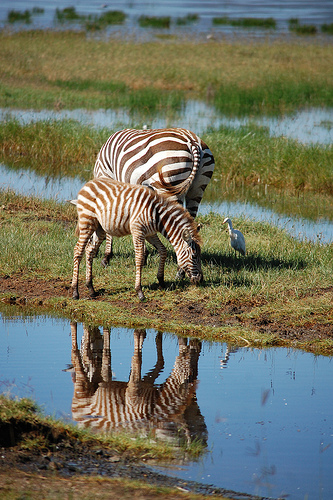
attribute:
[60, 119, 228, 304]
zebras — black, big, eating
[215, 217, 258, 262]
bird — tiny, small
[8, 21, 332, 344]
grass — green, high, thick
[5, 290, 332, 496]
water — blue, small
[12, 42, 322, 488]
grass — green 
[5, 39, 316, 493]
ground — muddy  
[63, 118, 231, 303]
zebra — tail , big , small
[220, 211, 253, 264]
bird — white 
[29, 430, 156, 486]
mud — water's edge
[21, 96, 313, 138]
surface — water's 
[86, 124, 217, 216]
zebra — wagging tail 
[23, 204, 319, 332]
grass — clumps  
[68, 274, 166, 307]
hooves — muddy, zebra's 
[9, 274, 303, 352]
bank — river 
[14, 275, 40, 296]
mud — dark 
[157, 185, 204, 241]
mane — brown  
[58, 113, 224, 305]
zebra — young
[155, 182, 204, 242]
hair — long 